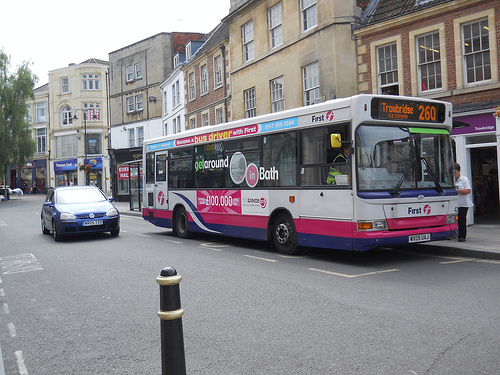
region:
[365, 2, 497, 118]
face of brick building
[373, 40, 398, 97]
open window on building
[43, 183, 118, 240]
front of blue car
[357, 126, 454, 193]
glass of bus windshield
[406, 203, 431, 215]
logo on front of bus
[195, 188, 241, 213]
pink and white sign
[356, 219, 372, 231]
orange light on bus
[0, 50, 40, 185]
green leaves on tree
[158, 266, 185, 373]
black pole with two rings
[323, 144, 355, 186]
driver in front of bus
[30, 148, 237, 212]
the car is blue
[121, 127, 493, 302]
the bus is red, white, and blue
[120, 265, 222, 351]
a pole is by the street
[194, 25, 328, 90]
the building has windows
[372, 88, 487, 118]
the number is on the front of the truck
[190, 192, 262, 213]
a red sign is on the bus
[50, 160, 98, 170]
a blue sign is on the building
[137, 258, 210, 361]
gold rings are around the pole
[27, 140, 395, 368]
the car is next to the bus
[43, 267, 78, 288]
gray cement on road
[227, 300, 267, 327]
gray cement on road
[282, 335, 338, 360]
gray cement on road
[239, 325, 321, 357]
gray cement on road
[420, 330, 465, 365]
gray cement on road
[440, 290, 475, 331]
gray cement on road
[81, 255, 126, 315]
gray cement on road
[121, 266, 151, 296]
gray cement on road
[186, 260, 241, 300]
gray cement on road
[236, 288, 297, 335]
gray cement on road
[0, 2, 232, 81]
light in daytime sky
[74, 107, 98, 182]
street lights on pole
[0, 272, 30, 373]
broken lines in road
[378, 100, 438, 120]
number and destination in orange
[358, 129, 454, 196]
windshield on bus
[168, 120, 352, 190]
windows on side of bus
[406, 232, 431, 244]
license plate on bumper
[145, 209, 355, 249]
pink and blue stripe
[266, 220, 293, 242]
Front tire of a bus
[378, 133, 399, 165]
the mirror of a bus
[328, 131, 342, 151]
the side mirror of a bus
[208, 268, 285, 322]
tarmac road in the street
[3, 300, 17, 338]
white dotted line on the tarmac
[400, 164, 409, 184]
the wiper of a bus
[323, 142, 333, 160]
the window of a bus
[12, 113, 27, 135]
green leaves of a tree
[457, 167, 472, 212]
a person standing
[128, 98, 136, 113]
a window on a building